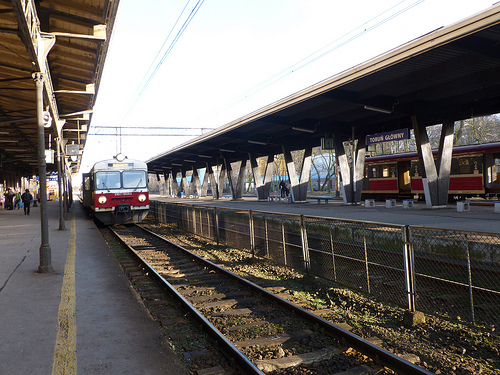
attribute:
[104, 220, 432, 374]
track — steel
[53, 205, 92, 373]
line — yellow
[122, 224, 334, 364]
track — train, steel, wood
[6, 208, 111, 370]
sidewalk — concrete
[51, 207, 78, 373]
line — yellow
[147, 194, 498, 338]
fence — metal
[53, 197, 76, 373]
line — yellow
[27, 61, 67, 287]
pole — metal